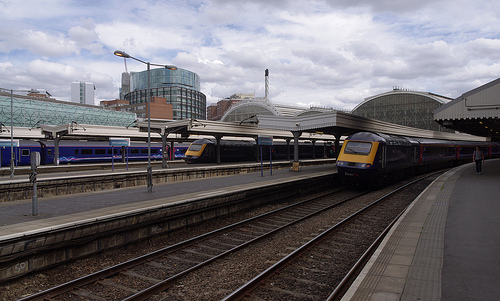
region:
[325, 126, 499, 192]
yellow and blue train on train track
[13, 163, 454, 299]
metal train tracks on ground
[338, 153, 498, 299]
raised and paved train platform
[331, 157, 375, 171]
headlights on front of train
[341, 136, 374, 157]
windshield on front of train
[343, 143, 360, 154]
windshield wiper blade on train windshield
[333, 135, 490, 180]
yellow train on the right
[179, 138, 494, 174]
yellow train on the left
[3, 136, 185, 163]
blue train in the background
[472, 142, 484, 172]
person standing on platform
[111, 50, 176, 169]
light in the middle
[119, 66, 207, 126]
glass building in the background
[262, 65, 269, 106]
tower in the background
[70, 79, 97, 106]
white building in the background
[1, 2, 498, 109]
cloudy and blue sky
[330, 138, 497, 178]
lights on the front of the train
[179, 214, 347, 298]
gravel under the tracks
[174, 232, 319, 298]
the gravel is dark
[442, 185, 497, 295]
the platform is paved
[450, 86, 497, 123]
the awning is white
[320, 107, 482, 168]
roof above the train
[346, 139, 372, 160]
one wiper on windshield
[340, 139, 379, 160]
train front is yellow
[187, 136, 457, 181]
two trains in the photo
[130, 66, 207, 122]
the building is glass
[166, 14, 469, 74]
the sky is cloudy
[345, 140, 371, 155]
glass window on train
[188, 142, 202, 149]
glass window on train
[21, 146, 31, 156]
glass window on train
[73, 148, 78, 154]
glass window on train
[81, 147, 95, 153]
glass window on train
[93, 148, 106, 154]
glass window on train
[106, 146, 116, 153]
glass window on train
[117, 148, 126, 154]
glass window on train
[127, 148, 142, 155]
glass window on train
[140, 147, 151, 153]
glass window on train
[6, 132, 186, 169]
The train to the far left is blue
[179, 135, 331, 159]
The train in the middle is yellow and silver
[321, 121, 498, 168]
The train to the far left is yellow and silver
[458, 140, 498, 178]
A man is walking on the platform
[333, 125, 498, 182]
Yellow and black train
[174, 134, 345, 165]
Yellow and black train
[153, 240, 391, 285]
These tracks are empty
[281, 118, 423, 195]
The yellow side of the train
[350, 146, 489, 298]
No one is waiting on the train